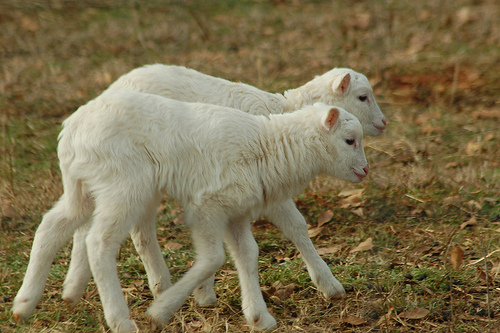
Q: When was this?
A: Daytime.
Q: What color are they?
A: White.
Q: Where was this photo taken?
A: A farm.